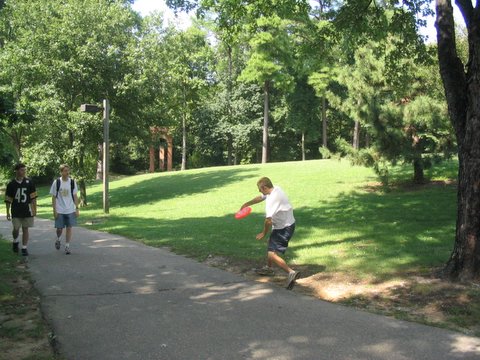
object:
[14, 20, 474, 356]
park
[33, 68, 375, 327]
scene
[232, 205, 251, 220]
disc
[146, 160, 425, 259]
lawn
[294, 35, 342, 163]
trees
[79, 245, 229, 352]
sidewalk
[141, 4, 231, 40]
sky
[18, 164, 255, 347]
sidewalk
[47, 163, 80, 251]
man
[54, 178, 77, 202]
backpack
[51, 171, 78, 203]
straps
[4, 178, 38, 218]
jersey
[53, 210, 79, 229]
shorts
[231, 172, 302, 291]
man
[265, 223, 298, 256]
shorts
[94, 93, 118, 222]
fixture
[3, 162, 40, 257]
man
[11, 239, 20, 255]
shoes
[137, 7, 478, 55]
sky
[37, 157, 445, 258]
light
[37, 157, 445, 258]
shadow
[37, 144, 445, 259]
slope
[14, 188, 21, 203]
number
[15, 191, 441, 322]
shadow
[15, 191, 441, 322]
walkway